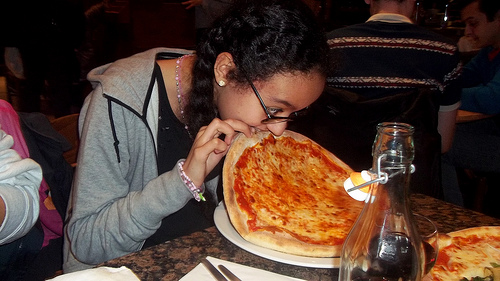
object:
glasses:
[243, 75, 292, 125]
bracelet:
[179, 163, 205, 201]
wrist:
[178, 164, 203, 193]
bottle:
[337, 122, 425, 280]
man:
[322, 0, 460, 156]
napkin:
[178, 254, 317, 280]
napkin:
[47, 263, 149, 281]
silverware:
[217, 264, 240, 281]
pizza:
[421, 226, 500, 281]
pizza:
[223, 129, 368, 257]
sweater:
[0, 127, 43, 245]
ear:
[214, 52, 236, 87]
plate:
[214, 203, 341, 269]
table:
[48, 185, 500, 281]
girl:
[65, 6, 328, 274]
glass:
[375, 213, 438, 280]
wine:
[371, 238, 432, 268]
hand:
[183, 118, 254, 188]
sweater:
[63, 47, 223, 274]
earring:
[219, 81, 225, 86]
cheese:
[236, 135, 372, 243]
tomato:
[236, 147, 253, 168]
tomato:
[437, 250, 450, 266]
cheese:
[429, 233, 500, 280]